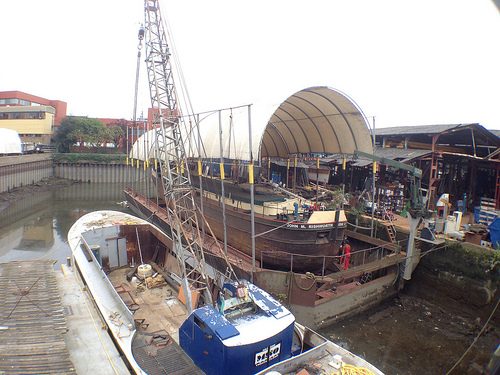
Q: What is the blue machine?
A: A crane.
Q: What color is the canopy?
A: White.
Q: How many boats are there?
A: Two.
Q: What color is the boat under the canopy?
A: Brown.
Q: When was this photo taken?
A: During the daytime.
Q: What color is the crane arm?
A: Silver.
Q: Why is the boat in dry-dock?
A: To be fixed.